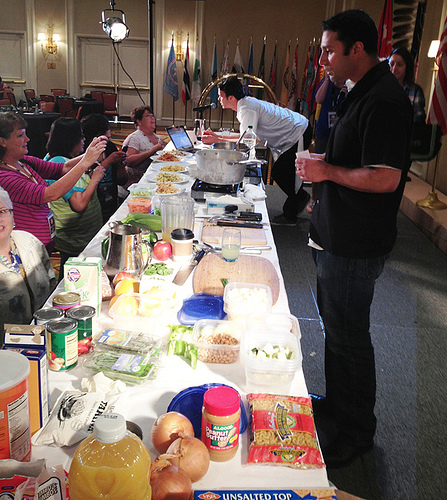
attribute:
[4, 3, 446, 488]
room — lecture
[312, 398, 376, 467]
shoes — black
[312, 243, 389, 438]
pants — blue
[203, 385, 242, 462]
jar — red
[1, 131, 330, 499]
table — white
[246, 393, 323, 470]
pasta — macaroni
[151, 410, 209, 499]
onions — brown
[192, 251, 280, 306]
cutting board — wooden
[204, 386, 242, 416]
lid — red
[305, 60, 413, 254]
shirt — black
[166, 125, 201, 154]
laptop — on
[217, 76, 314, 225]
person — presenting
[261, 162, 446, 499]
floor — grey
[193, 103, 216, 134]
microphone — black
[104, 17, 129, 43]
light — on